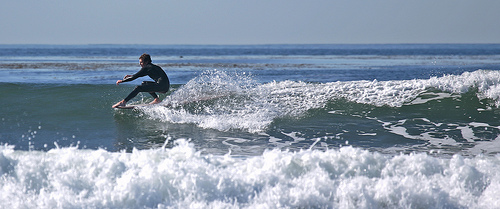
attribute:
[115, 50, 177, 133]
wetsuit — black